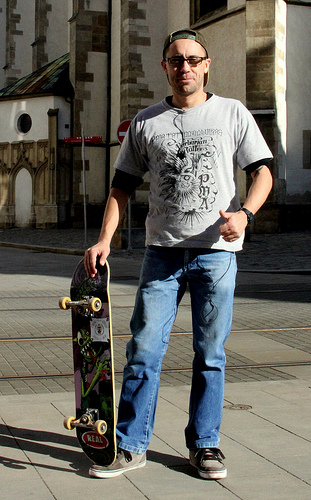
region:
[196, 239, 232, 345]
black cords on man's jeans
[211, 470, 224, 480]
tiny brown spot on edge of shoes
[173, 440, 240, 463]
black shoe laces in shoes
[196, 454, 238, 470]
gray top of shoes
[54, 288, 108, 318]
yellow wheels on skate board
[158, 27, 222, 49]
green edge of cap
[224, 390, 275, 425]
small round grate on ground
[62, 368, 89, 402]
purple color on back of skate board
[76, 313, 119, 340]
white square logo on bottom of board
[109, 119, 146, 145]
edge of red and white sign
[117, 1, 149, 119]
Exposed stone in the side of the building.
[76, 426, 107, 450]
A red and white sticker that says "Real."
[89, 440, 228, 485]
Gray sneakers with black laces.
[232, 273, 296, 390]
The street is made from bricks.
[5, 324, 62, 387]
Metal rails are embedded in the street.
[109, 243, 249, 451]
The man is wearing jeans.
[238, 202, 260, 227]
A black wristwatch.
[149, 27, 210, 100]
The man is wearing a hat.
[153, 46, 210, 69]
Glasses.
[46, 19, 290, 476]
The man is holding a skateboard.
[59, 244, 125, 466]
skate board with four wheels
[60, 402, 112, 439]
pair of skateboard wheels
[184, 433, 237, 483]
lace up sneaker shoe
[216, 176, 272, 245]
wrist watch on arm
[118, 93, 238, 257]
white t shirt with black graffic design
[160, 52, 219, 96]
man's face with glasses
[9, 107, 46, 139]
round window in wall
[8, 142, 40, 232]
sealed arched doorway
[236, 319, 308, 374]
trolley tracks in road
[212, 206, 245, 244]
hand with thumb pointing up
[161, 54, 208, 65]
men's eyeglasses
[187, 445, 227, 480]
men's gray shoe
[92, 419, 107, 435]
the wheel of a skateboard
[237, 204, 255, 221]
a man's wristwatch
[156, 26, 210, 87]
a man's green baseball cap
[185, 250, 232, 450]
the leg of a man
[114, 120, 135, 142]
a red and white sign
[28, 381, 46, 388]
a piece of a brick street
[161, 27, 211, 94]
the head of a man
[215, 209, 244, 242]
the hand of a man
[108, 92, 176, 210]
black shirt under gray shirt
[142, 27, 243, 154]
guy wearing cap backward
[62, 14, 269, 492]
guy holding skateboard in hand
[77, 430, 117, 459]
red and white label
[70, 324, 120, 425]
green, white, and purple design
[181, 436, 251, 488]
shoe with black lace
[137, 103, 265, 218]
gray shirt with black design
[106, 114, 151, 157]
red and white sign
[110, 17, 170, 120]
bricks on the building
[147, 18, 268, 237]
guy holding thumb up